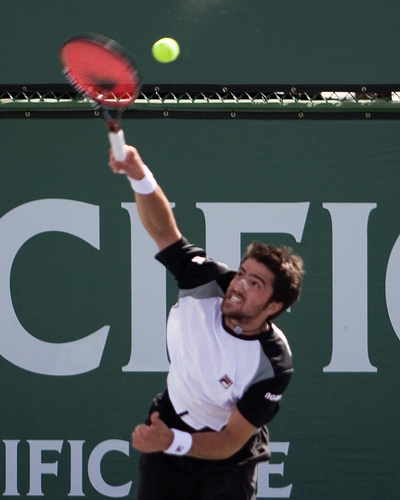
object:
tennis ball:
[151, 37, 180, 62]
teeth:
[229, 294, 242, 302]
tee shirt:
[154, 231, 295, 436]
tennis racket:
[58, 26, 144, 174]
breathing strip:
[239, 276, 249, 290]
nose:
[230, 273, 250, 295]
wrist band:
[162, 426, 195, 455]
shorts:
[137, 388, 271, 498]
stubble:
[219, 287, 271, 321]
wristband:
[127, 165, 158, 195]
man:
[108, 142, 306, 497]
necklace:
[227, 317, 264, 334]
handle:
[96, 105, 127, 174]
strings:
[59, 40, 137, 107]